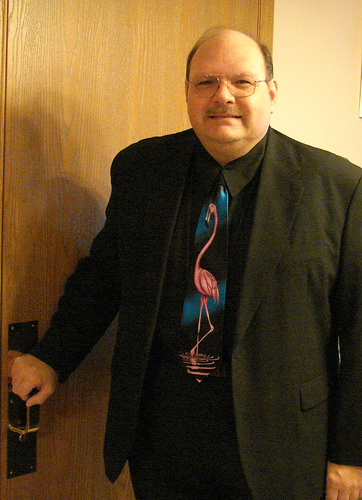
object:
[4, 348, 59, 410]
hand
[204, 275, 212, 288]
feathers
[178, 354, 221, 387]
pool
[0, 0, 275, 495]
door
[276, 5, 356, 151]
white wall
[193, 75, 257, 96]
frames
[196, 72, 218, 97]
lenses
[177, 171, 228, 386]
tie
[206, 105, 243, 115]
moustache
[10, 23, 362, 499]
man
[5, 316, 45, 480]
door handle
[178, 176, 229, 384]
necktie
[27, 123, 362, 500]
blazer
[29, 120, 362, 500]
suit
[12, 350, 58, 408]
hand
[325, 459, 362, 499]
hand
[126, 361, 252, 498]
trousers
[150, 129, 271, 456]
shirt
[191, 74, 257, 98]
eyeglasses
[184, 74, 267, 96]
metal framed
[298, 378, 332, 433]
pockets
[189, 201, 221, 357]
flamingo